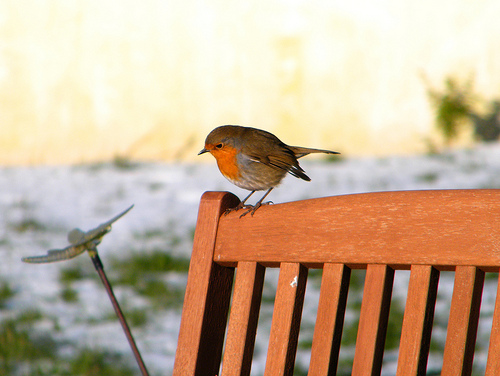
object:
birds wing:
[242, 123, 312, 182]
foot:
[237, 198, 273, 218]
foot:
[224, 195, 244, 215]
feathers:
[267, 143, 311, 179]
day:
[110, 22, 330, 109]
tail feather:
[289, 142, 344, 160]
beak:
[197, 147, 210, 156]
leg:
[252, 182, 272, 203]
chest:
[213, 146, 237, 180]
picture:
[2, 2, 496, 374]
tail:
[294, 142, 335, 159]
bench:
[173, 171, 495, 373]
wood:
[171, 184, 497, 372]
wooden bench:
[169, 185, 499, 374]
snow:
[25, 164, 171, 201]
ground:
[3, 158, 497, 373]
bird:
[190, 111, 329, 203]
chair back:
[151, 191, 496, 367]